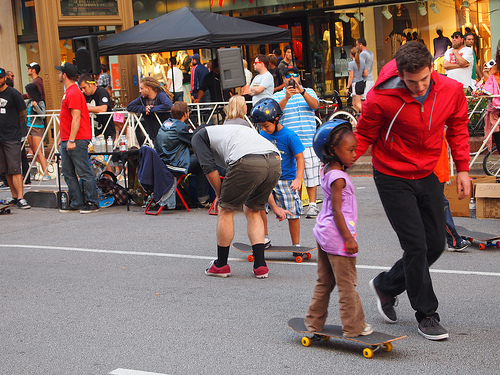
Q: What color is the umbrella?
A: Black.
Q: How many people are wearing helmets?
A: 2.